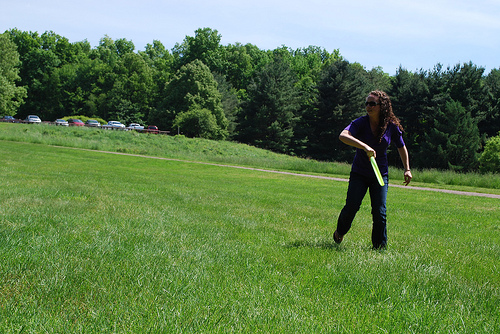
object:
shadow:
[281, 238, 348, 253]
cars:
[55, 119, 70, 127]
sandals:
[330, 240, 342, 253]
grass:
[0, 138, 497, 332]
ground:
[5, 122, 499, 332]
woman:
[333, 90, 412, 250]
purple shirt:
[343, 113, 405, 176]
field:
[1, 25, 500, 175]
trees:
[170, 108, 223, 141]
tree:
[155, 58, 227, 141]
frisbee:
[370, 155, 386, 186]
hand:
[403, 170, 414, 186]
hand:
[364, 147, 376, 158]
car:
[129, 123, 145, 131]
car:
[107, 117, 124, 129]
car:
[86, 119, 100, 127]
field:
[0, 137, 500, 334]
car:
[147, 126, 158, 135]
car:
[68, 118, 85, 126]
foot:
[330, 240, 342, 252]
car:
[22, 115, 42, 124]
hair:
[366, 90, 407, 144]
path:
[0, 137, 497, 199]